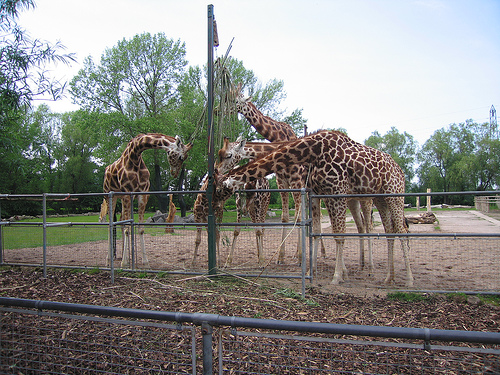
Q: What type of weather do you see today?
A: It is cloudy.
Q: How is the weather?
A: It is cloudy.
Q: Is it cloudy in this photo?
A: Yes, it is cloudy.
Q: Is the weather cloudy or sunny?
A: It is cloudy.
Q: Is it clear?
A: No, it is cloudy.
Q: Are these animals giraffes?
A: Yes, all the animals are giraffes.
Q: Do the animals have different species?
A: No, all the animals are giraffes.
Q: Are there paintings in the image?
A: No, there are no paintings.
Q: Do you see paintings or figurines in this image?
A: No, there are no paintings or figurines.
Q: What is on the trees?
A: The leaves are on the trees.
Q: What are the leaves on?
A: The leaves are on the trees.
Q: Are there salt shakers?
A: No, there are no salt shakers.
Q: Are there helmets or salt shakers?
A: No, there are no salt shakers or helmets.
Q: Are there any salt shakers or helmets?
A: No, there are no salt shakers or helmets.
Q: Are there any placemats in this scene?
A: No, there are no placemats.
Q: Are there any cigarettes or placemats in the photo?
A: No, there are no placemats or cigarettes.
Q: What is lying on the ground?
A: The stump is lying on the ground.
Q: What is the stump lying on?
A: The stump is lying on the ground.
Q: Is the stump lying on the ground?
A: Yes, the stump is lying on the ground.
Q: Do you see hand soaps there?
A: No, there are no hand soaps.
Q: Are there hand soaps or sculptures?
A: No, there are no hand soaps or sculptures.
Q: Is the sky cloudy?
A: Yes, the sky is cloudy.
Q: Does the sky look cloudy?
A: Yes, the sky is cloudy.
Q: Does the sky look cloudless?
A: No, the sky is cloudy.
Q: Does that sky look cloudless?
A: No, the sky is cloudy.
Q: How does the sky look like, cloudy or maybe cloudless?
A: The sky is cloudy.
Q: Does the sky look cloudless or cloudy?
A: The sky is cloudy.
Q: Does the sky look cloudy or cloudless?
A: The sky is cloudy.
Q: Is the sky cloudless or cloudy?
A: The sky is cloudy.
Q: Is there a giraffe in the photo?
A: Yes, there is a giraffe.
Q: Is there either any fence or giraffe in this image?
A: Yes, there is a giraffe.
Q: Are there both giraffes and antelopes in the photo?
A: No, there is a giraffe but no antelopes.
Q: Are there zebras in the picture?
A: No, there are no zebras.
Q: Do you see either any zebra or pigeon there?
A: No, there are no zebras or pigeons.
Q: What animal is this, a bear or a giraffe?
A: This is a giraffe.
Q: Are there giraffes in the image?
A: Yes, there is a giraffe.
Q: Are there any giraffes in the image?
A: Yes, there is a giraffe.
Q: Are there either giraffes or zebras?
A: Yes, there is a giraffe.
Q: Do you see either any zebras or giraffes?
A: Yes, there is a giraffe.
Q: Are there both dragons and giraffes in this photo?
A: No, there is a giraffe but no dragons.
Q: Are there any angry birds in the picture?
A: No, there are no angry birds.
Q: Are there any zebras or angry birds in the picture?
A: No, there are no angry birds or zebras.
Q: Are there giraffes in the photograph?
A: Yes, there is a giraffe.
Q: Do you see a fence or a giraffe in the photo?
A: Yes, there is a giraffe.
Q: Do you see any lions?
A: No, there are no lions.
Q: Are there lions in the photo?
A: No, there are no lions.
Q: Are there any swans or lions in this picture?
A: No, there are no lions or swans.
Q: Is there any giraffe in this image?
A: Yes, there is a giraffe.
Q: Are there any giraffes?
A: Yes, there is a giraffe.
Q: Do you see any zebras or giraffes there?
A: Yes, there is a giraffe.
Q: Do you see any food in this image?
A: Yes, there is food.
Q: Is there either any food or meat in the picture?
A: Yes, there is food.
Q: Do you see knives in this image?
A: No, there are no knives.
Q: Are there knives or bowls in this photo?
A: No, there are no knives or bowls.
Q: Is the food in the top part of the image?
A: Yes, the food is in the top of the image.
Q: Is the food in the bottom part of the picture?
A: No, the food is in the top of the image.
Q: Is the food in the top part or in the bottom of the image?
A: The food is in the top of the image.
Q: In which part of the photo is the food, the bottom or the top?
A: The food is in the top of the image.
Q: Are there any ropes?
A: No, there are no ropes.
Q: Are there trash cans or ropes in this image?
A: No, there are no ropes or trash cans.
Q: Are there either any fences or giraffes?
A: Yes, there is a giraffe.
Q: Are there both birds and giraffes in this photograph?
A: No, there is a giraffe but no birds.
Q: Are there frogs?
A: No, there are no frogs.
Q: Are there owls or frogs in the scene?
A: No, there are no frogs or owls.